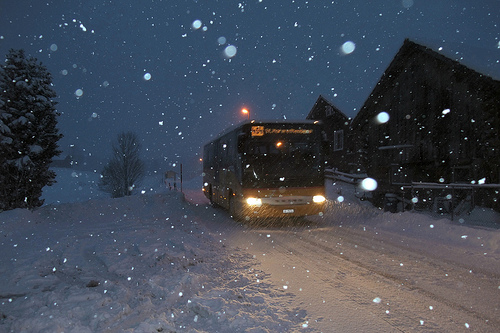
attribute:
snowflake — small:
[139, 66, 159, 83]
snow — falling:
[145, 26, 420, 171]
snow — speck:
[57, 257, 75, 264]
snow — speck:
[153, 113, 170, 127]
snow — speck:
[372, 102, 390, 124]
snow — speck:
[278, 275, 293, 301]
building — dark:
[296, 22, 498, 235]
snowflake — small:
[359, 174, 379, 194]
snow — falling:
[3, 4, 496, 331]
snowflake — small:
[223, 42, 237, 59]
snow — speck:
[6, 168, 498, 330]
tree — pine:
[3, 39, 70, 219]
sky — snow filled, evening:
[224, 15, 383, 91]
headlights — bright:
[223, 165, 352, 227]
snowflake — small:
[337, 37, 357, 56]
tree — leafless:
[93, 124, 152, 203]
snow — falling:
[352, 161, 382, 193]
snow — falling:
[133, 50, 444, 212]